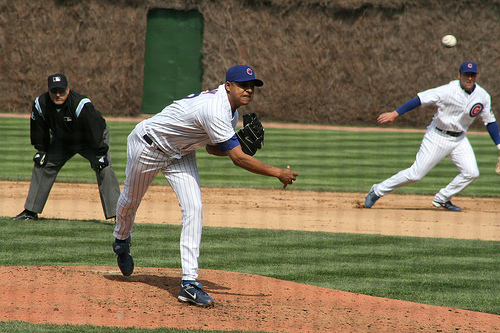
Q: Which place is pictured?
A: It is a lawn.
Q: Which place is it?
A: It is a lawn.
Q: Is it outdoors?
A: Yes, it is outdoors.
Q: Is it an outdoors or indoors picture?
A: It is outdoors.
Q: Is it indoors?
A: No, it is outdoors.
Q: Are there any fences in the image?
A: No, there are no fences.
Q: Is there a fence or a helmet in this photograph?
A: No, there are no fences or helmets.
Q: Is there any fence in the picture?
A: No, there are no fences.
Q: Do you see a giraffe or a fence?
A: No, there are no fences or giraffes.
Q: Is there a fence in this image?
A: No, there are no fences.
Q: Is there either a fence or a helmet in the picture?
A: No, there are no fences or helmets.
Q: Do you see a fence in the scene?
A: No, there are no fences.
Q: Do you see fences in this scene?
A: No, there are no fences.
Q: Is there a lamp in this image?
A: No, there are no lamps.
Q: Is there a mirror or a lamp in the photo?
A: No, there are no lamps or mirrors.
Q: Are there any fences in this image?
A: No, there are no fences.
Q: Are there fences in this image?
A: No, there are no fences.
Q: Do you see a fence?
A: No, there are no fences.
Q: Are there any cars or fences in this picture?
A: No, there are no fences or cars.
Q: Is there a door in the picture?
A: Yes, there is a door.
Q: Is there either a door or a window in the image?
A: Yes, there is a door.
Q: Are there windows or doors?
A: Yes, there is a door.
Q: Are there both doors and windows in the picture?
A: No, there is a door but no windows.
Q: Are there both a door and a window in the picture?
A: No, there is a door but no windows.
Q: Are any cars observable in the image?
A: No, there are no cars.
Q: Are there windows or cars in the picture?
A: No, there are no cars or windows.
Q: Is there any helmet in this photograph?
A: No, there are no helmets.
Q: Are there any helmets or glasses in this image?
A: No, there are no helmets or glasses.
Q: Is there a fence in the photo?
A: No, there are no fences.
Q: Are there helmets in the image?
A: No, there are no helmets.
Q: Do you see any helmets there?
A: No, there are no helmets.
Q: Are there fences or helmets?
A: No, there are no helmets or fences.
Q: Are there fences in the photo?
A: No, there are no fences.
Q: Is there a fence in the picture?
A: No, there are no fences.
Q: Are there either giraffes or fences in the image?
A: No, there are no fences or giraffes.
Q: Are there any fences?
A: No, there are no fences.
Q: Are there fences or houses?
A: No, there are no fences or houses.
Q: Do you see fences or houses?
A: No, there are no fences or houses.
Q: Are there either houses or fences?
A: No, there are no fences or houses.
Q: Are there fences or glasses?
A: No, there are no fences or glasses.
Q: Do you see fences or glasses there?
A: No, there are no fences or glasses.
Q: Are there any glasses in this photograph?
A: No, there are no glasses.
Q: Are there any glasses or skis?
A: No, there are no glasses or skis.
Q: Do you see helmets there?
A: No, there are no helmets.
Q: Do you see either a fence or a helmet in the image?
A: No, there are no helmets or fences.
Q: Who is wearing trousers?
A: The player is wearing trousers.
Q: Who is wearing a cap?
A: The player is wearing a cap.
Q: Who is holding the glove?
A: The player is holding the glove.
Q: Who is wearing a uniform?
A: The player is wearing a uniform.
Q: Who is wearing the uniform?
A: The player is wearing a uniform.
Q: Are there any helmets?
A: No, there are no helmets.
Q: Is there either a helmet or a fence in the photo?
A: No, there are no helmets or fences.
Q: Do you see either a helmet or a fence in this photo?
A: No, there are no helmets or fences.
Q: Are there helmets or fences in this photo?
A: No, there are no helmets or fences.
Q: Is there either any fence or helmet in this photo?
A: No, there are no helmets or fences.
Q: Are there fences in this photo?
A: No, there are no fences.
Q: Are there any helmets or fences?
A: No, there are no fences or helmets.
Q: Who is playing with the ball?
A: The player is playing with the ball.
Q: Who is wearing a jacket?
A: The player is wearing a jacket.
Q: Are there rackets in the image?
A: No, there are no rackets.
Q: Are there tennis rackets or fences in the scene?
A: No, there are no tennis rackets or fences.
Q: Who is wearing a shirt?
A: The player is wearing a shirt.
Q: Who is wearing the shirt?
A: The player is wearing a shirt.